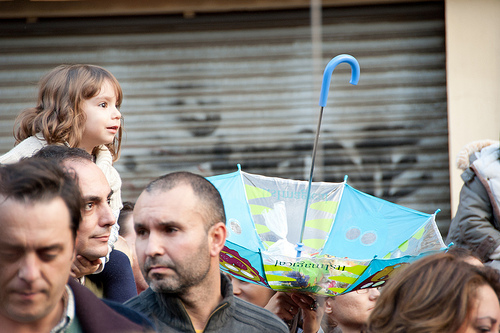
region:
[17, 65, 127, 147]
Excited little girl's face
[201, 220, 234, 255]
Left ear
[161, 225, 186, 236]
Man's left eye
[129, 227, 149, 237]
Man's right eye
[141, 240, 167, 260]
Man's nose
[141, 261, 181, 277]
Man's closed mouth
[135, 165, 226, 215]
Man's short black hair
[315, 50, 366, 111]
Blue handle on umbrela upsided down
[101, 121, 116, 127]
Little girl's excited open mouth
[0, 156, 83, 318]
Head of man looking down with closed eye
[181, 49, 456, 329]
a woman holds an umbrella upside down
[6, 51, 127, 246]
a young girl looks into the distance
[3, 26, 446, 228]
a garage style door is behind the group of people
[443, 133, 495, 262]
a portion of a persons jacket can be seen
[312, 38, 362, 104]
the umbrella's handle is blue in color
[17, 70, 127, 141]
the young girl has curls in her hair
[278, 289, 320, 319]
the woman wears two rings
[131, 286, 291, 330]
the man wears a grey sweater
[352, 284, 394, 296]
this person wears glasses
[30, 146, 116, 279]
man looking to the left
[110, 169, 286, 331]
man looking to the right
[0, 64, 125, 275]
girl wearing a white top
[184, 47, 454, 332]
umbrella with a blue handle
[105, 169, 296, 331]
man wearing a grey shirt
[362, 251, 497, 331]
woman with brunette hair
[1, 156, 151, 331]
man looking down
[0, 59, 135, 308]
girl on her fathers shoulders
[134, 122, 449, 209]
graffiti on a building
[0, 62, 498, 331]
crowd of people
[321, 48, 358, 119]
blue color handle of the umbrella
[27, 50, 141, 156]
a child looking something eagerly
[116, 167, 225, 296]
head of the person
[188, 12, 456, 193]
shutter of the shop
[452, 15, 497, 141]
cream color coated wall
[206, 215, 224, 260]
ear of the person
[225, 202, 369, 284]
multi-color umbrella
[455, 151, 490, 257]
person wearing grey color jacket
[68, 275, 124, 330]
a person wearing brown color jacket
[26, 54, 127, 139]
head of the child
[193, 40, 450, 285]
the umbrella is open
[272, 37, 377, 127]
the handle is blue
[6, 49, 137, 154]
the girl`s hair is brown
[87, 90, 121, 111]
the eyes are open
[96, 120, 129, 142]
the lips are pink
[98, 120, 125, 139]
the mouth is slightly open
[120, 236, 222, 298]
the man has a shadow beard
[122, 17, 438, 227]
a gate is behind the people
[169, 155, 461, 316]
the umbrella is multi colored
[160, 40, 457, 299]
overturned small umbrella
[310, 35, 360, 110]
blue plastic umbrella handle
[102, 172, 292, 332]
man in gray sweater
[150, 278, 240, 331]
gray sweater collar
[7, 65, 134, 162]
child on mans back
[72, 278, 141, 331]
maroon coat collar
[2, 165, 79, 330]
man with brown hair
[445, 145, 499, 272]
gray winter jacket sleeve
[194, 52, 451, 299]
umbrella is open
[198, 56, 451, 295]
umbrella is upside down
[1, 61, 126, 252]
child looks to right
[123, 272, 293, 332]
sweater worn by human